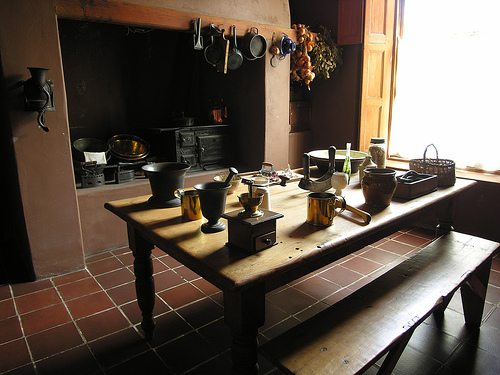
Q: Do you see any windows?
A: Yes, there is a window.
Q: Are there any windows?
A: Yes, there is a window.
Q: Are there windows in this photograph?
A: Yes, there is a window.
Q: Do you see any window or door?
A: Yes, there is a window.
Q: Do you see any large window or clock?
A: Yes, there is a large window.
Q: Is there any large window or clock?
A: Yes, there is a large window.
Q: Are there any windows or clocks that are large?
A: Yes, the window is large.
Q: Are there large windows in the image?
A: Yes, there is a large window.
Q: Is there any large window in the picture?
A: Yes, there is a large window.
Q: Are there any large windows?
A: Yes, there is a large window.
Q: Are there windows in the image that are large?
A: Yes, there is a window that is large.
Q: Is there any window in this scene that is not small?
A: Yes, there is a large window.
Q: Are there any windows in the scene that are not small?
A: Yes, there is a large window.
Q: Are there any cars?
A: No, there are no cars.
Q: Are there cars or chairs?
A: No, there are no cars or chairs.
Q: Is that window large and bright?
A: Yes, the window is large and bright.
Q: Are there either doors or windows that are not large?
A: No, there is a window but it is large.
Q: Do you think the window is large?
A: Yes, the window is large.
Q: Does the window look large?
A: Yes, the window is large.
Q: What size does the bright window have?
A: The window has large size.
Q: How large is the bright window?
A: The window is large.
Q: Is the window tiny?
A: No, the window is large.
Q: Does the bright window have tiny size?
A: No, the window is large.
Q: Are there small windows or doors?
A: No, there is a window but it is large.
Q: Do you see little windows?
A: No, there is a window but it is large.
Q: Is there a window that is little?
A: No, there is a window but it is large.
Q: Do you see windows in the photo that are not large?
A: No, there is a window but it is large.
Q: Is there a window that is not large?
A: No, there is a window but it is large.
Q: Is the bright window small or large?
A: The window is large.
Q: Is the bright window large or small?
A: The window is large.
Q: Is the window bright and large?
A: Yes, the window is bright and large.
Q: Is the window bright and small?
A: No, the window is bright but large.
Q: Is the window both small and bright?
A: No, the window is bright but large.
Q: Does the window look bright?
A: Yes, the window is bright.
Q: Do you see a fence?
A: No, there are no fences.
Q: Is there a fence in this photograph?
A: No, there are no fences.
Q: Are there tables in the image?
A: Yes, there is a table.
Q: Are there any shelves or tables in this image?
A: Yes, there is a table.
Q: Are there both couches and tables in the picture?
A: No, there is a table but no couches.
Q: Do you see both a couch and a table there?
A: No, there is a table but no couches.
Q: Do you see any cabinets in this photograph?
A: No, there are no cabinets.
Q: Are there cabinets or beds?
A: No, there are no cabinets or beds.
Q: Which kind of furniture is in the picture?
A: The furniture is a table.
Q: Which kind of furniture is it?
A: The piece of furniture is a table.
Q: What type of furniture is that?
A: This is a table.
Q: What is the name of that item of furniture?
A: This is a table.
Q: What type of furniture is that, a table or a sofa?
A: This is a table.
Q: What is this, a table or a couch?
A: This is a table.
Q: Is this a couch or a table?
A: This is a table.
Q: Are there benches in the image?
A: Yes, there is a bench.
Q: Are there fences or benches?
A: Yes, there is a bench.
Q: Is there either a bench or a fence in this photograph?
A: Yes, there is a bench.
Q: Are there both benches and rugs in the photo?
A: No, there is a bench but no rugs.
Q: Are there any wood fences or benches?
A: Yes, there is a wood bench.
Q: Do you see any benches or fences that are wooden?
A: Yes, the bench is wooden.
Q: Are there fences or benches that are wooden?
A: Yes, the bench is wooden.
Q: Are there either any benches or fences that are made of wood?
A: Yes, the bench is made of wood.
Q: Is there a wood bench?
A: Yes, there is a bench that is made of wood.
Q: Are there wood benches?
A: Yes, there is a bench that is made of wood.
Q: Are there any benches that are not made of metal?
A: Yes, there is a bench that is made of wood.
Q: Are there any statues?
A: No, there are no statues.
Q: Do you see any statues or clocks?
A: No, there are no statues or clocks.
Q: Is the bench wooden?
A: Yes, the bench is wooden.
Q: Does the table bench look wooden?
A: Yes, the bench is wooden.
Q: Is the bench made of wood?
A: Yes, the bench is made of wood.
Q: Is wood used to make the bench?
A: Yes, the bench is made of wood.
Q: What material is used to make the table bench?
A: The bench is made of wood.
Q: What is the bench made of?
A: The bench is made of wood.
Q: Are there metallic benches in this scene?
A: No, there is a bench but it is wooden.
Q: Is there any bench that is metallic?
A: No, there is a bench but it is wooden.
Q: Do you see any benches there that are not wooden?
A: No, there is a bench but it is wooden.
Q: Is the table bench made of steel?
A: No, the bench is made of wood.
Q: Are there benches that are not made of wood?
A: No, there is a bench but it is made of wood.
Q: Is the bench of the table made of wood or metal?
A: The bench is made of wood.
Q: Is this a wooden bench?
A: Yes, this is a wooden bench.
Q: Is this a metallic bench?
A: No, this is a wooden bench.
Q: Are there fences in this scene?
A: No, there are no fences.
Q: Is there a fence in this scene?
A: No, there are no fences.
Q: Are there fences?
A: No, there are no fences.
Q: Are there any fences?
A: No, there are no fences.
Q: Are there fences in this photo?
A: No, there are no fences.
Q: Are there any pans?
A: Yes, there is a pan.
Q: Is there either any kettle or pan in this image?
A: Yes, there is a pan.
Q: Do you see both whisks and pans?
A: No, there is a pan but no whisks.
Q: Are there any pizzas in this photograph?
A: No, there are no pizzas.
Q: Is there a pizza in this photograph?
A: No, there are no pizzas.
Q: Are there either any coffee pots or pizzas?
A: No, there are no pizzas or coffee pots.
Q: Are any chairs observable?
A: No, there are no chairs.